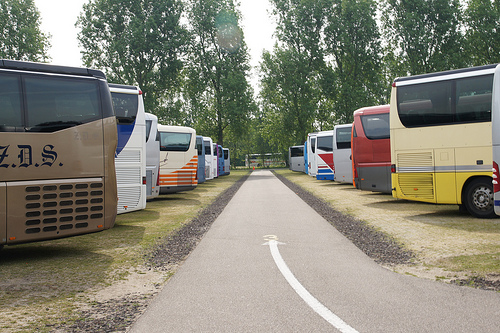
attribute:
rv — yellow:
[380, 67, 498, 221]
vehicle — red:
[349, 102, 390, 192]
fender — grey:
[347, 161, 392, 191]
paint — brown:
[85, 142, 90, 162]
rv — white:
[315, 129, 335, 180]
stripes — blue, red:
[316, 149, 336, 180]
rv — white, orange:
[154, 123, 199, 193]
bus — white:
[314, 129, 332, 179]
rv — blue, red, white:
[303, 131, 337, 185]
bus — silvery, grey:
[328, 123, 355, 188]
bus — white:
[153, 120, 200, 190]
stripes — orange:
[158, 154, 200, 189]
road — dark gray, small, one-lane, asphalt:
[125, 165, 499, 330]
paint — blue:
[313, 162, 335, 183]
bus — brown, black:
[0, 57, 118, 242]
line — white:
[265, 230, 312, 312]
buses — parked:
[1, 51, 498, 248]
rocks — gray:
[364, 231, 384, 253]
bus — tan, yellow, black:
[386, 61, 498, 217]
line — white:
[255, 224, 372, 331]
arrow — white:
[261, 236, 362, 331]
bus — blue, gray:
[169, 111, 315, 221]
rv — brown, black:
[0, 56, 120, 251]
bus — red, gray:
[350, 105, 393, 197]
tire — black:
[460, 163, 495, 217]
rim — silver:
[468, 188, 494, 208]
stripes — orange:
[162, 157, 198, 191]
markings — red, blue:
[311, 153, 338, 185]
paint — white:
[135, 137, 140, 151]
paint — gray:
[151, 139, 156, 149]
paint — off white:
[175, 157, 184, 162]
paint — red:
[368, 142, 377, 152]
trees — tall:
[117, 7, 482, 79]